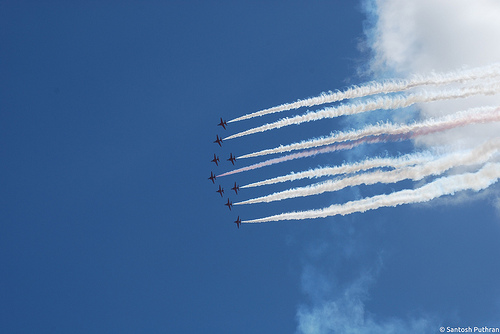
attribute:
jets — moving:
[207, 117, 252, 229]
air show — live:
[199, 74, 499, 226]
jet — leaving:
[209, 112, 264, 234]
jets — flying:
[188, 95, 268, 235]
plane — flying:
[214, 113, 226, 131]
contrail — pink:
[225, 63, 496, 125]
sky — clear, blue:
[51, 88, 153, 223]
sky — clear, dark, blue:
[0, 14, 496, 328]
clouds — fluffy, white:
[295, 220, 467, 332]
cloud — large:
[357, 3, 499, 155]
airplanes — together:
[213, 113, 228, 130]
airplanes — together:
[207, 135, 226, 147]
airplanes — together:
[203, 151, 240, 166]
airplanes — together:
[205, 168, 240, 198]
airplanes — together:
[221, 198, 245, 231]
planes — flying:
[204, 114, 245, 231]